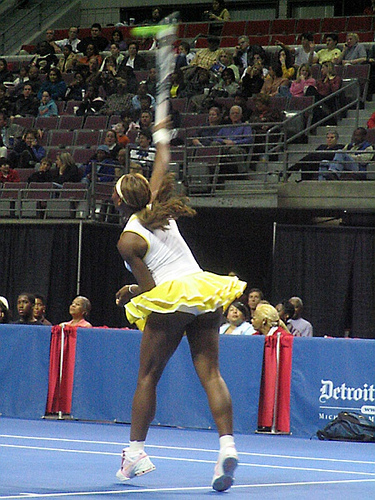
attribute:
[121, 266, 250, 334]
skirt — yellow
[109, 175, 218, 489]
player — tennis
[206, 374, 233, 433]
calves — strong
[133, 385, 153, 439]
calves — strong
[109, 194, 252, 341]
outfit — yellow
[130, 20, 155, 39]
ball — hot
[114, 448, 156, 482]
tennis shoe — white and pink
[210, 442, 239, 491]
tennis shoe — white and pink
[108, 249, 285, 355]
skirt — yellow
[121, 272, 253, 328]
skirt — yellow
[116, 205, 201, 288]
top — white